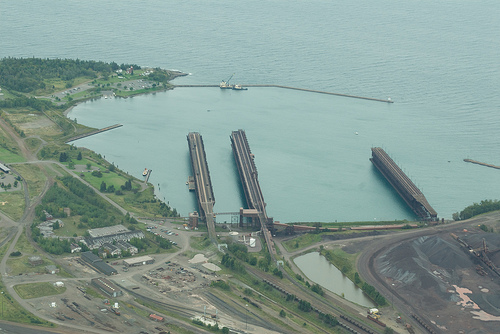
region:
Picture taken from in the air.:
[19, 37, 497, 328]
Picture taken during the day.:
[13, 34, 430, 326]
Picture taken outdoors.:
[28, 39, 490, 329]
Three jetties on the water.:
[172, 106, 486, 244]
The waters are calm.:
[206, 31, 408, 68]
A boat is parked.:
[219, 76, 254, 98]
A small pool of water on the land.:
[306, 256, 344, 298]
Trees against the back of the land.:
[16, 60, 88, 87]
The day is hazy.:
[32, 16, 388, 238]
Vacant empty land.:
[405, 243, 469, 299]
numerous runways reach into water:
[162, 108, 448, 225]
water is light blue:
[234, 77, 384, 207]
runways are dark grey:
[164, 85, 288, 260]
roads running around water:
[53, 207, 323, 331]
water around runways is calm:
[278, 49, 386, 223]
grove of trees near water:
[30, 173, 143, 258]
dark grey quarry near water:
[375, 219, 489, 325]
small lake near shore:
[299, 245, 391, 317]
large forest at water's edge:
[2, 57, 138, 88]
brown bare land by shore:
[3, 103, 51, 168]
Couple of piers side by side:
[182, 126, 272, 229]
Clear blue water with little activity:
[155, 0, 495, 221]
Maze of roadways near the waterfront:
[0, 215, 495, 330]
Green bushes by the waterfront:
[0, 55, 140, 95]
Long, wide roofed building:
[80, 220, 135, 240]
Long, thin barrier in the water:
[176, 75, 396, 105]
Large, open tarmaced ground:
[376, 235, 491, 330]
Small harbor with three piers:
[1, 1, 496, 326]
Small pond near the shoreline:
[285, 245, 382, 317]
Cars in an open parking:
[143, 217, 188, 247]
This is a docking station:
[358, 133, 451, 238]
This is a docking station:
[220, 118, 293, 279]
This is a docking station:
[177, 123, 219, 260]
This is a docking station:
[183, 72, 405, 119]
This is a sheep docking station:
[350, 137, 445, 239]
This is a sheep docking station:
[222, 114, 290, 262]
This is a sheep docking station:
[174, 125, 217, 262]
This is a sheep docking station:
[172, 69, 437, 121]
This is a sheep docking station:
[455, 150, 496, 175]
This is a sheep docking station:
[70, 108, 134, 153]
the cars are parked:
[144, 223, 186, 251]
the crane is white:
[212, 78, 251, 95]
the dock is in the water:
[363, 140, 445, 219]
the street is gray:
[26, 273, 57, 281]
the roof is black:
[98, 276, 114, 292]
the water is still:
[167, 88, 247, 122]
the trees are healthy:
[18, 53, 82, 81]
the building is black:
[81, 249, 120, 279]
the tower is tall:
[186, 205, 198, 231]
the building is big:
[81, 219, 150, 241]